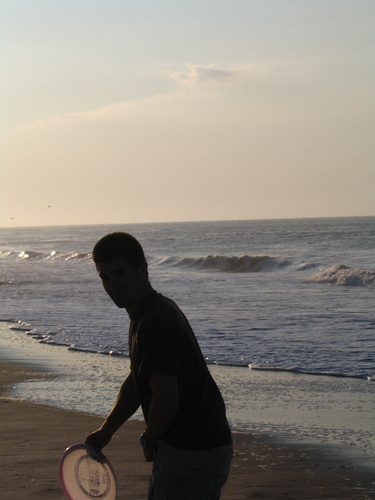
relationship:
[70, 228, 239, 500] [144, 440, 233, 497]
man has shorts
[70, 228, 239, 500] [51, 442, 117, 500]
man has frisbee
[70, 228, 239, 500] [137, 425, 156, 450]
man has watch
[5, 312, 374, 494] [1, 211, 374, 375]
shore next to ocean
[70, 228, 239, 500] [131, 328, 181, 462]
man has arm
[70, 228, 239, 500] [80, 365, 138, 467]
man has arm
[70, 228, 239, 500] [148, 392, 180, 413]
man has elbow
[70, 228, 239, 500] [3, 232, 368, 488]
man on beach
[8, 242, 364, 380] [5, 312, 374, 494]
waves on sand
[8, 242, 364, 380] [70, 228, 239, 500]
waves behind man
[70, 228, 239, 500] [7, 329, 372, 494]
man on sand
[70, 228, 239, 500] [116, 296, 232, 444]
man has shirt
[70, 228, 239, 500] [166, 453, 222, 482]
man has pocket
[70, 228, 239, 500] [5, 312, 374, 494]
man on shore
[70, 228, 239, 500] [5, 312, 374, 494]
man by shore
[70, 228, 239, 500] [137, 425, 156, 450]
man wearing watch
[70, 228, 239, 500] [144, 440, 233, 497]
man has pants